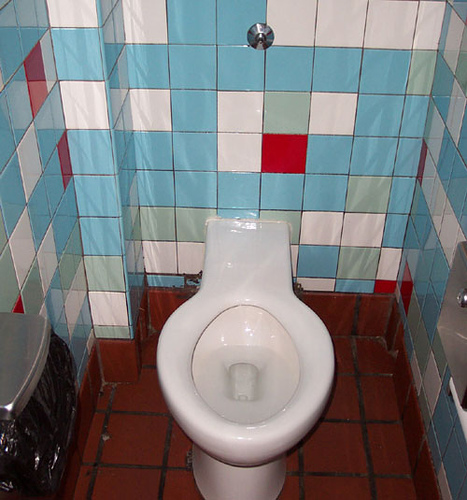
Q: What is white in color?
A: The toilet.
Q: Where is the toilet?
A: In the room.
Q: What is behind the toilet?
A: Tile wall.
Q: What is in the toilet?
A: Water.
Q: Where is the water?
A: In the toilet.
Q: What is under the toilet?
A: The tile.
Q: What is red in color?
A: Floor tile.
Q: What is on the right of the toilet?
A: Waste container.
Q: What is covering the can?
A: Large plastic cover.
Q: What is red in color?
A: Some tiles.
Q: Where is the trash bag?
A: In the trash bin.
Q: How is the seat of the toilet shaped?
A: Oval.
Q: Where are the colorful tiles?
A: On the walls.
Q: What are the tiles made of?
A: Ceramic.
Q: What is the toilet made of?
A: Porcelain.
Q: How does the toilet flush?
A: Button on wall.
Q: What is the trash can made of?
A: Metal.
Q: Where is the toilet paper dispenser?
A: Right side.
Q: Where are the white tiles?
A: On the walls.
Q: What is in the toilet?
A: Clean water.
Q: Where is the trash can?
A: In a restroom.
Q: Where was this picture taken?
A: A bathroom.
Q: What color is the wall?
A: Blue, white and red.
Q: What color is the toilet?
A: White.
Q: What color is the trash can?
A: Silver.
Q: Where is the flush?
A: The wall.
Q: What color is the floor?
A: Orange.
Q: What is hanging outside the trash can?
A: A trash bag.